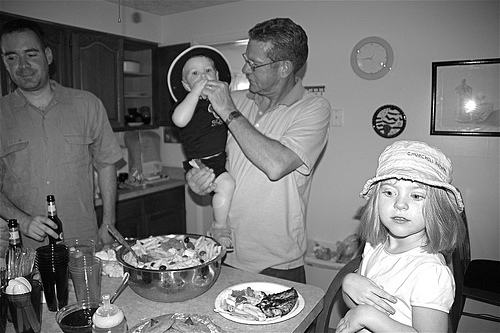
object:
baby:
[171, 52, 235, 252]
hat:
[166, 44, 234, 102]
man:
[0, 26, 123, 259]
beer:
[42, 194, 68, 250]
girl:
[330, 158, 467, 332]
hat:
[359, 139, 467, 216]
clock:
[350, 35, 394, 79]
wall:
[160, 0, 499, 264]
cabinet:
[71, 28, 191, 127]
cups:
[66, 255, 105, 309]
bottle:
[86, 293, 132, 332]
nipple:
[93, 294, 115, 316]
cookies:
[147, 316, 175, 332]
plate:
[126, 310, 226, 332]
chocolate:
[148, 318, 195, 326]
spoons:
[13, 280, 39, 332]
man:
[186, 17, 330, 281]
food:
[212, 284, 302, 324]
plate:
[211, 279, 307, 327]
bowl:
[114, 233, 226, 303]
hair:
[1, 24, 49, 65]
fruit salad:
[123, 234, 223, 269]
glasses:
[241, 51, 290, 72]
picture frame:
[428, 57, 500, 138]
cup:
[2, 291, 43, 331]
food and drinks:
[0, 219, 301, 332]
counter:
[0, 239, 325, 332]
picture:
[370, 103, 407, 139]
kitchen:
[0, 0, 500, 333]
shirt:
[220, 74, 332, 275]